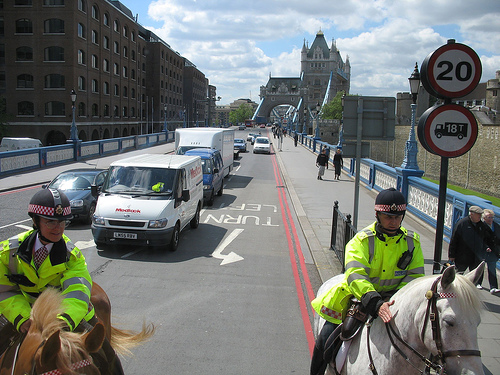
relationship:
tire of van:
[190, 204, 204, 230] [90, 151, 205, 253]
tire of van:
[168, 223, 182, 252] [90, 151, 205, 253]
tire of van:
[218, 179, 227, 196] [169, 124, 238, 181]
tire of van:
[207, 187, 217, 204] [169, 124, 238, 181]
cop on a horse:
[310, 187, 426, 374] [394, 279, 497, 366]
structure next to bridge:
[288, 25, 358, 130] [261, 105, 349, 224]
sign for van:
[394, 35, 491, 173] [90, 154, 203, 251]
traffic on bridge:
[26, 119, 278, 256] [1, 90, 496, 372]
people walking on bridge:
[447, 202, 494, 279] [10, 118, 498, 373]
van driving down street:
[99, 156, 209, 250] [10, 121, 334, 365]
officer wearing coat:
[1, 183, 140, 373] [0, 231, 112, 341]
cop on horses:
[310, 187, 426, 374] [306, 260, 488, 367]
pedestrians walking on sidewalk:
[271, 121, 498, 298] [269, 124, 498, 374]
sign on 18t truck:
[421, 105, 478, 155] [440, 119, 464, 136]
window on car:
[48, 170, 105, 192] [39, 167, 109, 218]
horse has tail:
[1, 172, 118, 367] [106, 314, 161, 363]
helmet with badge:
[371, 187, 413, 212] [389, 204, 400, 214]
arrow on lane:
[212, 215, 260, 275] [0, 126, 325, 371]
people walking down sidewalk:
[270, 125, 346, 181] [312, 191, 326, 258]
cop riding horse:
[310, 187, 426, 374] [428, 269, 448, 342]